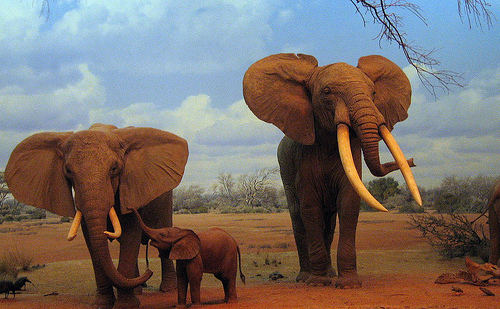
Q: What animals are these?
A: Elephants.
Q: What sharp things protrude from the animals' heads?
A: Tusks.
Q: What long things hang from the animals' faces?
A: Trunks.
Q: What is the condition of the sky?
A: Slightly cloudy.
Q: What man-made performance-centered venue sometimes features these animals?
A: The circus.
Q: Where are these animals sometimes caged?
A: Zoos.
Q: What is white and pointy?
A: Elephant tusk.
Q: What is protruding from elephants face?
A: Tusk.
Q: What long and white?
A: Tusk.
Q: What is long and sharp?
A: Tusk.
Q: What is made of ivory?
A: Tusk.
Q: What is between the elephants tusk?
A: Trunk.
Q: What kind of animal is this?
A: Elephant.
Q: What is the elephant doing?
A: Walking.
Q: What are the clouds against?
A: Blue sky.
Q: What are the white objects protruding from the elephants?
A: Tusks.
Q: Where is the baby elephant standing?
A: Next to adult elephant.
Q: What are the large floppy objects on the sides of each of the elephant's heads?
A: Ears.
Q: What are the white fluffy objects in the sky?
A: Clouds.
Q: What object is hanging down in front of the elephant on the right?
A: Tree branches.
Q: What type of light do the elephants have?
A: Daylight.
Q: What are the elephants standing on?
A: Ground.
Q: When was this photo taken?
A: Daytime.